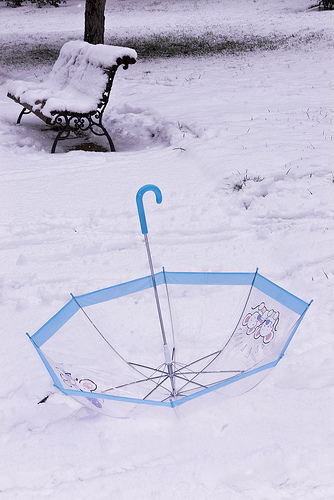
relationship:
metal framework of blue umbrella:
[90, 347, 244, 399] [25, 183, 314, 421]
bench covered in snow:
[7, 40, 135, 151] [6, 2, 333, 494]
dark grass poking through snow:
[221, 170, 266, 192] [6, 2, 333, 494]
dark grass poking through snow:
[175, 116, 204, 139] [6, 2, 333, 494]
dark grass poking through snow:
[256, 102, 332, 154] [6, 2, 333, 494]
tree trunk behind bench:
[80, 0, 106, 42] [7, 40, 135, 151]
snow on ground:
[4, 431, 320, 495] [32, 422, 233, 498]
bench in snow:
[5, 39, 137, 153] [6, 2, 333, 494]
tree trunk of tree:
[84, 0, 105, 42] [71, 3, 127, 52]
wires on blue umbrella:
[95, 348, 244, 412] [25, 183, 314, 421]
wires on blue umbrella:
[223, 264, 313, 367] [25, 183, 314, 421]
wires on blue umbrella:
[23, 266, 179, 390] [25, 183, 314, 421]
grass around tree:
[105, 24, 231, 59] [58, 0, 135, 62]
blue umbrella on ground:
[25, 181, 314, 420] [3, 1, 332, 498]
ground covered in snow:
[3, 1, 332, 498] [6, 2, 333, 494]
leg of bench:
[49, 127, 118, 153] [7, 40, 135, 151]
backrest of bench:
[53, 41, 130, 91] [7, 40, 135, 151]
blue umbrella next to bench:
[25, 183, 314, 421] [7, 40, 135, 151]